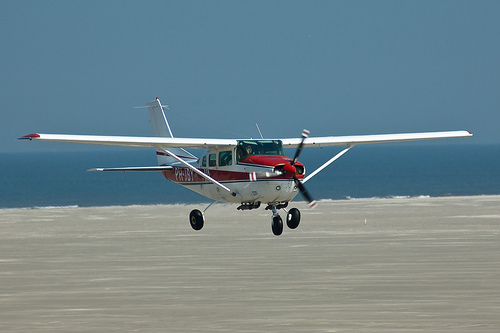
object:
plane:
[17, 96, 473, 236]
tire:
[271, 214, 283, 236]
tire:
[284, 205, 302, 229]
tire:
[188, 206, 204, 230]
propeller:
[250, 128, 319, 207]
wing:
[15, 128, 475, 151]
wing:
[83, 164, 172, 174]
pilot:
[240, 144, 255, 157]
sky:
[1, 1, 498, 205]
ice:
[2, 193, 497, 331]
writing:
[172, 166, 195, 181]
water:
[1, 140, 498, 208]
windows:
[196, 151, 231, 168]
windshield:
[233, 142, 280, 159]